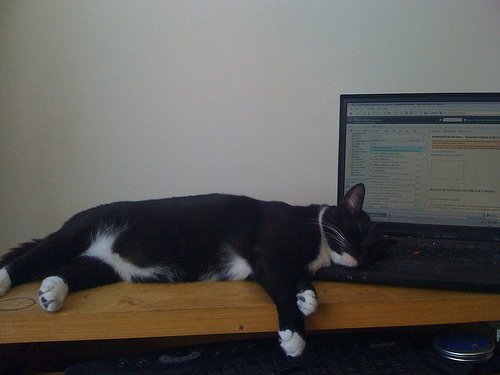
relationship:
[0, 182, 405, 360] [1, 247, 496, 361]
black/white cat on desk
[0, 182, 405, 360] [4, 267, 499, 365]
black/white cat on desk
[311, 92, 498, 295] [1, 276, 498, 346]
laptop on desk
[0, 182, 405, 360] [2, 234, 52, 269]
black/white cat has tail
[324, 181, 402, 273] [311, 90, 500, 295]
head on laptop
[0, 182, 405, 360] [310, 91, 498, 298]
black/white cat on computer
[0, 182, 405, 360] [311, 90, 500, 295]
black/white cat on laptop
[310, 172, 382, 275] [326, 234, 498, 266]
head on keyboard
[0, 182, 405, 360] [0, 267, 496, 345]
black/white cat sleeping on desk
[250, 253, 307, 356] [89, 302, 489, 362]
leg hanging over edge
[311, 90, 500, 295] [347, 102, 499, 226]
laptop with screen